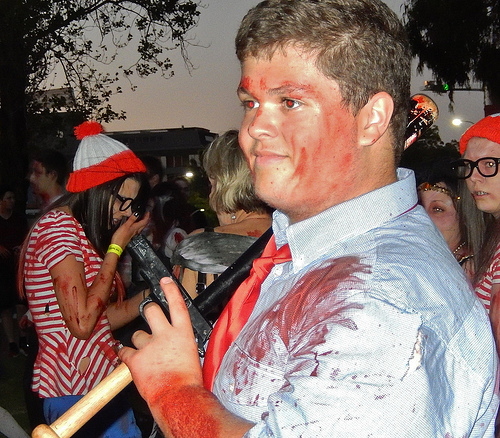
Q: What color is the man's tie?
A: Red.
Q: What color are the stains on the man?
A: Red.